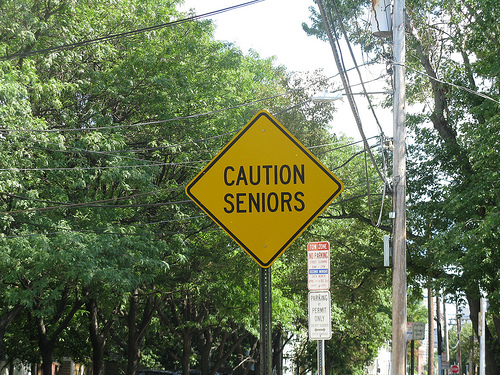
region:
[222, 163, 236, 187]
a letter is written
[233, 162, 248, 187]
a letter is written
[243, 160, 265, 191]
a letter is written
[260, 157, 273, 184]
a letter is written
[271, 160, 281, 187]
a letter is written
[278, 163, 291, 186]
a letter is written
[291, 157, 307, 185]
a letter is written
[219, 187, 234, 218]
a letter is written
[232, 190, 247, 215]
a letter is written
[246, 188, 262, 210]
a letter is written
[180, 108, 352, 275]
yellow sign with the letter c in it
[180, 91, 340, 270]
yellow sign with the letter a in it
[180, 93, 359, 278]
yellow sign with the letter u in it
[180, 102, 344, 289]
yellow sign with the letter t in it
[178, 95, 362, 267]
yellow sign with the letter i in it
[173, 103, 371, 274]
yellow sign with the letter o in it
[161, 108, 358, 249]
yellow sign with the letter n in it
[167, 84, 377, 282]
yellow sign with the letter s in it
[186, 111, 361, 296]
yellow sign with the letter e in it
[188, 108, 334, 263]
yellow and black caution diamond sign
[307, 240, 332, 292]
white red and blue no parking sign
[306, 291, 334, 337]
green and white parking permit only sign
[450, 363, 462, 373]
stop sign in distance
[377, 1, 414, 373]
tall wooden electrical pole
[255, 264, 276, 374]
green metal support pole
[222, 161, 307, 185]
black caution lettering on sign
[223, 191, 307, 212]
black seniors lettering on sign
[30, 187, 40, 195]
green leaf of tree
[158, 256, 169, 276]
green leaf of tree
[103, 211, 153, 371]
a tree in a distance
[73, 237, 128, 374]
a tree in a distance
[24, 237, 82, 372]
a tree in a distance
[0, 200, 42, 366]
a tree in a distance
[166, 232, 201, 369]
a tree in a distance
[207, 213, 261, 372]
a tree in a distance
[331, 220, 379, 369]
a tree in a distance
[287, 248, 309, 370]
a tree in a distance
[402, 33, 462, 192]
a tree in a distance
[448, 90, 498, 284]
a tree in a distance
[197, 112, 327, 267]
The sign is shaped like a diamond.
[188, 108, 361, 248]
The sign is yellow.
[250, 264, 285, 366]
the sign is on a iron pole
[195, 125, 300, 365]
The yellow sign is on a pole.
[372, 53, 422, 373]
The utility pole is wood.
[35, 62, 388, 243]
Wires running from the pole.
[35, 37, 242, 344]
The trees are tall and green.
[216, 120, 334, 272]
The sign says caution seniors.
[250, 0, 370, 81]
The sky is clear and blue.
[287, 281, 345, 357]
The sign is black and white.